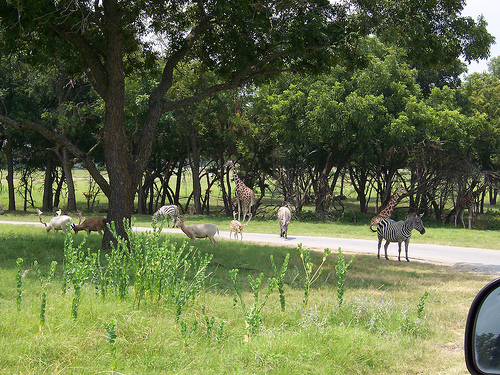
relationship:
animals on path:
[38, 183, 492, 253] [2, 216, 499, 275]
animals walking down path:
[367, 210, 425, 263] [2, 214, 499, 287]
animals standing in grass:
[367, 210, 425, 263] [374, 260, 407, 282]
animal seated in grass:
[367, 185, 408, 227] [24, 235, 353, 370]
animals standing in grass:
[367, 210, 425, 263] [206, 310, 333, 353]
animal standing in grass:
[173, 204, 220, 248] [165, 262, 425, 358]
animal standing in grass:
[67, 212, 112, 237] [265, 287, 374, 368]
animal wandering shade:
[221, 159, 257, 222] [228, 250, 271, 266]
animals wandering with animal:
[367, 210, 425, 263] [221, 159, 257, 222]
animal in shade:
[367, 185, 408, 227] [327, 195, 446, 222]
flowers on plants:
[222, 269, 389, 373] [263, 261, 348, 308]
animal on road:
[368, 212, 429, 263] [1, 219, 498, 285]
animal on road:
[275, 204, 296, 239] [1, 219, 498, 285]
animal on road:
[228, 220, 251, 241] [1, 219, 498, 285]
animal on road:
[173, 215, 221, 245] [1, 219, 498, 285]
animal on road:
[150, 202, 189, 229] [1, 219, 498, 285]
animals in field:
[367, 210, 425, 263] [86, 234, 291, 372]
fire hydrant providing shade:
[304, 50, 416, 195] [221, 237, 271, 277]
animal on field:
[365, 207, 429, 261] [0, 167, 499, 374]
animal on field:
[270, 202, 295, 240] [0, 167, 499, 374]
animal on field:
[169, 212, 222, 246] [0, 167, 499, 374]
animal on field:
[222, 212, 254, 237] [0, 167, 499, 374]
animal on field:
[31, 204, 74, 238] [0, 167, 499, 374]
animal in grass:
[221, 159, 257, 222] [23, 241, 389, 355]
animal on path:
[273, 201, 293, 238] [0, 221, 499, 277]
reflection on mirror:
[467, 328, 497, 370] [468, 283, 496, 372]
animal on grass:
[221, 159, 257, 222] [1, 166, 499, 251]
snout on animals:
[419, 227, 429, 238] [367, 210, 425, 263]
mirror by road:
[463, 272, 498, 374] [1, 217, 498, 278]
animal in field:
[80, 188, 97, 203] [0, 170, 499, 247]